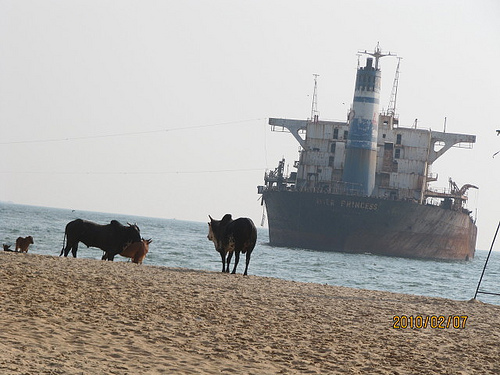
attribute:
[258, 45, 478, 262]
ship — large, big, brown, rusty, princess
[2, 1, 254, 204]
sky — grey, hazy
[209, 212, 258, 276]
bull — looking, large, brown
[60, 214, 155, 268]
animal — large, dark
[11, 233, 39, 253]
animal — standing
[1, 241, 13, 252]
dog — walking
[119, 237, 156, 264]
animal — large, brown, standing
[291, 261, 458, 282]
water — calm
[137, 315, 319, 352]
sand — brown, trampled